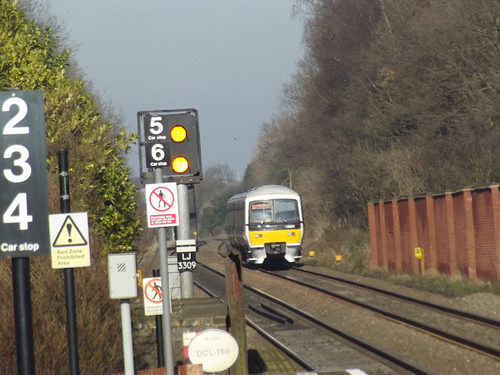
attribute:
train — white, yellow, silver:
[224, 182, 304, 271]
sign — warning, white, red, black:
[146, 182, 179, 230]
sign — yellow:
[46, 211, 91, 272]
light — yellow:
[170, 127, 187, 143]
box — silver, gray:
[108, 252, 139, 301]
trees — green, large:
[0, 1, 499, 374]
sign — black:
[1, 90, 52, 258]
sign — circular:
[188, 328, 239, 372]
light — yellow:
[173, 156, 189, 173]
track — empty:
[189, 239, 434, 375]